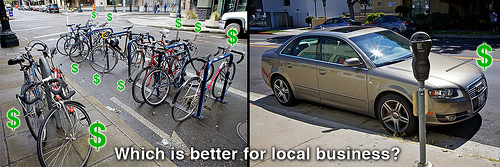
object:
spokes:
[41, 106, 96, 163]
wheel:
[171, 77, 203, 122]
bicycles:
[139, 34, 211, 106]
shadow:
[251, 93, 483, 150]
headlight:
[427, 87, 464, 99]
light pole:
[1, 0, 21, 48]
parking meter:
[406, 29, 435, 165]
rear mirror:
[342, 57, 363, 67]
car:
[45, 3, 60, 14]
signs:
[90, 71, 104, 86]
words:
[113, 146, 130, 160]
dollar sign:
[85, 119, 109, 151]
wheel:
[375, 92, 418, 137]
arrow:
[107, 93, 194, 157]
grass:
[446, 149, 499, 162]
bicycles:
[56, 19, 101, 56]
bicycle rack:
[156, 41, 186, 95]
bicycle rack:
[122, 35, 156, 83]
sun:
[368, 46, 388, 61]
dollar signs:
[70, 61, 80, 75]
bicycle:
[169, 44, 244, 124]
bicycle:
[17, 57, 94, 165]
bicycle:
[7, 39, 51, 142]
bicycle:
[89, 22, 137, 73]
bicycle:
[124, 31, 157, 80]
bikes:
[128, 29, 192, 104]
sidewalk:
[0, 33, 175, 166]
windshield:
[347, 30, 412, 68]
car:
[313, 17, 362, 29]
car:
[363, 15, 415, 33]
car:
[218, 10, 246, 39]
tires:
[140, 69, 172, 106]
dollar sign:
[473, 42, 494, 71]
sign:
[192, 20, 204, 33]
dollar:
[226, 26, 240, 47]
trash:
[111, 110, 122, 114]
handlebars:
[42, 77, 77, 99]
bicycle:
[64, 19, 111, 63]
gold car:
[260, 25, 489, 137]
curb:
[21, 37, 181, 167]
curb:
[246, 95, 499, 166]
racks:
[31, 55, 65, 128]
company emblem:
[474, 82, 487, 92]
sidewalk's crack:
[250, 101, 499, 166]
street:
[0, 7, 175, 46]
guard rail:
[192, 53, 235, 120]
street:
[248, 28, 499, 160]